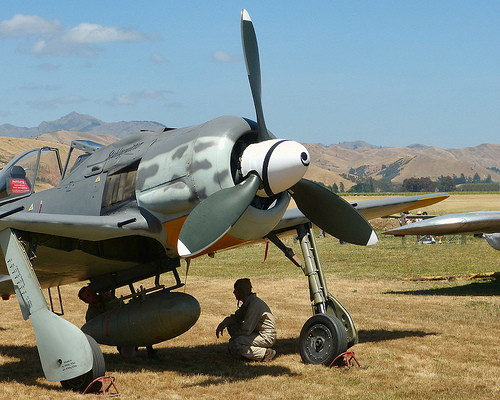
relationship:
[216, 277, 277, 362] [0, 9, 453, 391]
man sits under fighter plane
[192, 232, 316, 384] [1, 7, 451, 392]
man sitting under jet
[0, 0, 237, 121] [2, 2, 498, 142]
cloud in sky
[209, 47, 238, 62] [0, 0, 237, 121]
cloud in cloud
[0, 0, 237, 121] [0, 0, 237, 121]
cloud in cloud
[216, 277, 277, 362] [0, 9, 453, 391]
man under fighter plane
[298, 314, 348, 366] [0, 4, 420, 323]
black wheel on plane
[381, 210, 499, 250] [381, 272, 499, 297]
plane has shadow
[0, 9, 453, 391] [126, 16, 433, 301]
fighter plane has propeller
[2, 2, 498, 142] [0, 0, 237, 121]
sky has cloud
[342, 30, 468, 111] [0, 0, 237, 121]
blue sky has cloud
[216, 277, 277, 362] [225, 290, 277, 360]
man wearing flight suit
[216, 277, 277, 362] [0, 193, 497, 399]
man kneeling on ground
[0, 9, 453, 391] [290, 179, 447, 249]
fighter plane has wing